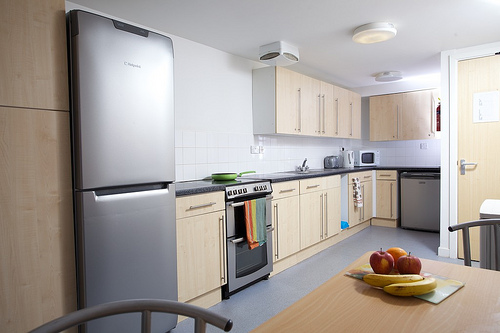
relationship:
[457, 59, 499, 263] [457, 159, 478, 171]
door with handle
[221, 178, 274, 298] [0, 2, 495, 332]
stove for kitchen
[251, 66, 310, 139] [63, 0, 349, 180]
cabinets on wall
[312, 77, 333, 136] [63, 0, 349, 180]
cabinets on wall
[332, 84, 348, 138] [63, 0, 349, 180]
cabinets on wall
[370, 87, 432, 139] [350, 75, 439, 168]
cabinets on wall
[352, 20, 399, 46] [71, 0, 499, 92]
light on ceiling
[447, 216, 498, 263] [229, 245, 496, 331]
chair in front of table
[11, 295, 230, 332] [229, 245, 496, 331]
chair in front of table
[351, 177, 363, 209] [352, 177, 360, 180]
towel hanging on handle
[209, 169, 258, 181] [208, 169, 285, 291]
pan on a stove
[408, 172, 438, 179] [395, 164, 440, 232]
handle on a dishwasher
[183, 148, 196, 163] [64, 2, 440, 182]
tile on a wall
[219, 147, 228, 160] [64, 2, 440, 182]
tile on a wall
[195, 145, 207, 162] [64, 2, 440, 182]
tile on a wall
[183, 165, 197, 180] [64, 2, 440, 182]
tile on a wall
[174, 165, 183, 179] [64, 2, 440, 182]
tile on a wall